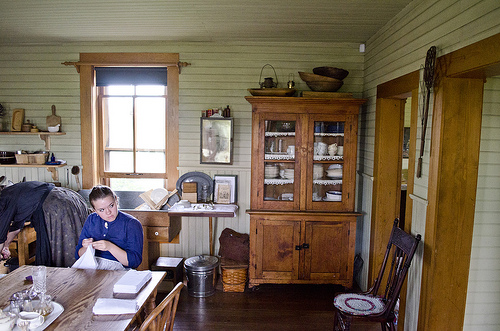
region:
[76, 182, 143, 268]
Woman sitting in dining room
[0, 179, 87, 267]
Person bending over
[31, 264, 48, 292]
Glass on the table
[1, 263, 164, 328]
Wood table in the dining room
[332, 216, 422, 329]
Chair with chair cushion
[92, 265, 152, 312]
Cloths on the table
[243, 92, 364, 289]
Brown wood cabinet in the corner.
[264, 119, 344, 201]
Tableware in the cabinet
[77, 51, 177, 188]
Window with wood frame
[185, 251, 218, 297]
Metal bucket on the floor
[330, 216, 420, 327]
an old wooden chair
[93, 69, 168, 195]
a long window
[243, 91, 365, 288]
a brown wooden hutch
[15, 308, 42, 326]
a small white tea cup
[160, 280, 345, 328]
dark brown hardwood floor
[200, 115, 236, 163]
a black cabinet handle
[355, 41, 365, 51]
a white alarm sensor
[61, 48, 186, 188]
a brown window trim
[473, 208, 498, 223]
a white wall panel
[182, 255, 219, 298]
a small gray can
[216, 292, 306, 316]
clean hard wood floor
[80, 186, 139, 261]
woman sitting at a table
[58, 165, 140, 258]
dark haired woman sitting at a table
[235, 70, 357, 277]
wood china hutch in a house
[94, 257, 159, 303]
folded napkins on a table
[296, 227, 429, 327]
wood chair against a wall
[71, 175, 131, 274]
woman in an apron sitting at a table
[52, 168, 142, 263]
woman dressed in blue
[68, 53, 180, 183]
open window in a house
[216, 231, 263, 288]
basket on a floor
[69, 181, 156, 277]
Woman in blue at table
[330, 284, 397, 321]
Round cushion on chair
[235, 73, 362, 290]
Brown wooden cabinet holding plates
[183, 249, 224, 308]
Silver metal container on floor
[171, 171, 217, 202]
Gray platter plate on counter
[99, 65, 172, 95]
Blue window shade on top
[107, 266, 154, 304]
Stack of white linens on table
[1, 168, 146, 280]
Woman bent over beside other woman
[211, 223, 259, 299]
purse sits on a basket on the floor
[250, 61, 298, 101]
Oil lamp sits on top of cabinet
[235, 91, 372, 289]
a cabinet full of dishes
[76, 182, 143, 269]
a person sitting near the table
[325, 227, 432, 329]
a fancy brown chair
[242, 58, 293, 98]
a fancy brown basket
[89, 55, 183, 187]
a bright house window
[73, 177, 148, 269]
a person with a blue shirt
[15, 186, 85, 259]
a stack of clothing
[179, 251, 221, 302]
a silver trash can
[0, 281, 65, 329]
a stack of dishes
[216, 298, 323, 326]
a wooden floor